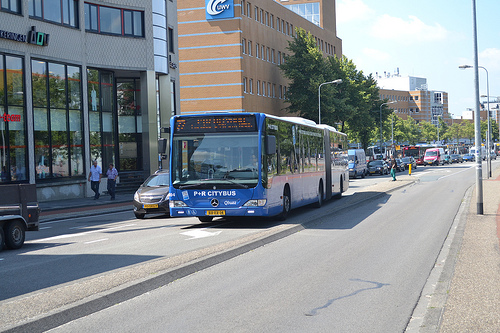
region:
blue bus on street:
[171, 110, 350, 225]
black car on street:
[131, 170, 168, 215]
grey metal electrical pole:
[476, 1, 483, 218]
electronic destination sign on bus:
[175, 116, 256, 130]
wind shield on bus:
[174, 138, 261, 183]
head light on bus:
[245, 198, 265, 208]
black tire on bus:
[281, 190, 292, 217]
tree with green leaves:
[284, 28, 349, 125]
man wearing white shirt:
[88, 159, 103, 196]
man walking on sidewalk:
[105, 163, 120, 200]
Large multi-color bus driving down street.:
[1, 10, 498, 330]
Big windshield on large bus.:
[168, 110, 358, 222]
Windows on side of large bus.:
[161, 103, 359, 225]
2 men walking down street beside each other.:
[1, 0, 144, 222]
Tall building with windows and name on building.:
[0, 2, 180, 222]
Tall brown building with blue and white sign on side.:
[175, 0, 343, 123]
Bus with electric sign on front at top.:
[168, 107, 351, 225]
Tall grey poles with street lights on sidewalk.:
[402, 0, 499, 332]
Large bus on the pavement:
[167, 121, 249, 203]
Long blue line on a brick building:
[178, 93, 248, 105]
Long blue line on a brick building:
[180, 80, 250, 94]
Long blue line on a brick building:
[175, 66, 247, 81]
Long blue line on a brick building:
[178, 56, 251, 63]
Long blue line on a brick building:
[179, 43, 245, 49]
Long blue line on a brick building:
[176, 25, 235, 42]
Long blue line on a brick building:
[179, 18, 241, 28]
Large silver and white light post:
[310, 64, 345, 117]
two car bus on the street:
[166, 119, 348, 224]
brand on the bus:
[209, 197, 219, 209]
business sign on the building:
[0, 25, 49, 47]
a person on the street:
[388, 155, 400, 178]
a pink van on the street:
[421, 147, 442, 164]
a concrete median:
[6, 177, 412, 329]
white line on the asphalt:
[83, 235, 108, 245]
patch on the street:
[308, 277, 393, 317]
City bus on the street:
[155, 87, 357, 228]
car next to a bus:
[135, 159, 175, 213]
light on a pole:
[456, 59, 493, 187]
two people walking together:
[76, 157, 118, 194]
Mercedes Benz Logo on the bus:
[209, 193, 219, 208]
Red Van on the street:
[422, 141, 449, 172]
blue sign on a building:
[200, 2, 239, 20]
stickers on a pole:
[468, 145, 484, 172]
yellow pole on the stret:
[403, 160, 415, 175]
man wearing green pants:
[383, 163, 403, 183]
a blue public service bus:
[166, 110, 351, 225]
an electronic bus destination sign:
[173, 115, 258, 130]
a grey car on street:
[128, 169, 170, 218]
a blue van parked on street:
[346, 147, 366, 177]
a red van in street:
[422, 147, 440, 164]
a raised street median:
[0, 179, 407, 331]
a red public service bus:
[401, 144, 433, 162]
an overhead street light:
[458, 62, 470, 69]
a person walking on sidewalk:
[88, 157, 100, 196]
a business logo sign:
[203, 0, 233, 19]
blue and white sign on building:
[198, 0, 240, 26]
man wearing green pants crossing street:
[385, 153, 400, 183]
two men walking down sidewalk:
[79, 159, 120, 203]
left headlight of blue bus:
[240, 192, 271, 214]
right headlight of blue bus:
[169, 194, 189, 212]